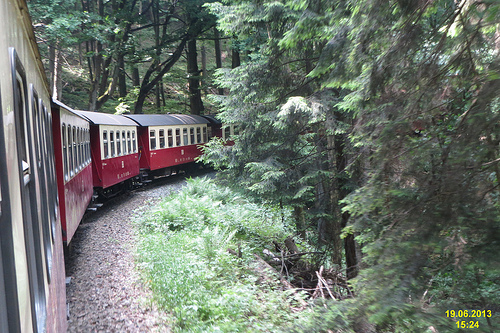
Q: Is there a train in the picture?
A: Yes, there is a train.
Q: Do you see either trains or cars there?
A: Yes, there is a train.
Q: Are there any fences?
A: No, there are no fences.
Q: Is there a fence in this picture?
A: No, there are no fences.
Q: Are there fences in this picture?
A: No, there are no fences.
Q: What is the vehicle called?
A: The vehicle is a train.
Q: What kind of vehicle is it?
A: The vehicle is a train.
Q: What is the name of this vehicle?
A: This is a train.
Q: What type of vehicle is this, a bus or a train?
A: This is a train.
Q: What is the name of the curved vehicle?
A: The vehicle is a train.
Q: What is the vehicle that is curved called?
A: The vehicle is a train.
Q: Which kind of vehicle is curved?
A: The vehicle is a train.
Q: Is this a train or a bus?
A: This is a train.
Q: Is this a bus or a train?
A: This is a train.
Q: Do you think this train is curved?
A: Yes, the train is curved.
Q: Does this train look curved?
A: Yes, the train is curved.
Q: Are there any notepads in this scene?
A: No, there are no notepads.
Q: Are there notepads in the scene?
A: No, there are no notepads.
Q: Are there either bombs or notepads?
A: No, there are no notepads or bombs.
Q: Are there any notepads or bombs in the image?
A: No, there are no notepads or bombs.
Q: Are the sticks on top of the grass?
A: Yes, the sticks are on top of the grass.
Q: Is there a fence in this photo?
A: No, there are no fences.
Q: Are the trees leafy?
A: Yes, the trees are leafy.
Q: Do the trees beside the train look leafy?
A: Yes, the trees are leafy.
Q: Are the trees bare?
A: No, the trees are leafy.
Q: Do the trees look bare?
A: No, the trees are leafy.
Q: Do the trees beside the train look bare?
A: No, the trees are leafy.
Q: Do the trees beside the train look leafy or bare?
A: The trees are leafy.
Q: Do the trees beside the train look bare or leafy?
A: The trees are leafy.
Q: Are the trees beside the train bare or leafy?
A: The trees are leafy.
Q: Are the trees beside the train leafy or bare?
A: The trees are leafy.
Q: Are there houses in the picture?
A: No, there are no houses.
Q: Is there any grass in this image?
A: Yes, there is grass.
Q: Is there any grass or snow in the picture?
A: Yes, there is grass.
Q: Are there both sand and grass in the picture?
A: No, there is grass but no sand.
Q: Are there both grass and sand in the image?
A: No, there is grass but no sand.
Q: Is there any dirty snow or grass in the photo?
A: Yes, there is dirty grass.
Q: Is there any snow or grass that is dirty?
A: Yes, the grass is dirty.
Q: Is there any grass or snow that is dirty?
A: Yes, the grass is dirty.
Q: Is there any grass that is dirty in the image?
A: Yes, there is dirty grass.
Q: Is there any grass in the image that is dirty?
A: Yes, there is grass that is dirty.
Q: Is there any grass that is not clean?
A: Yes, there is dirty grass.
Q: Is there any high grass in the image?
A: Yes, there is high grass.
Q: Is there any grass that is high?
A: Yes, there is grass that is high.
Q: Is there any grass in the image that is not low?
A: Yes, there is high grass.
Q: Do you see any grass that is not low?
A: Yes, there is high grass.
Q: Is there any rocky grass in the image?
A: Yes, there is rocky grass.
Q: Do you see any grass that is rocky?
A: Yes, there is rocky grass.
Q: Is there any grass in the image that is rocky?
A: Yes, there is grass that is rocky.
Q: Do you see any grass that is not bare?
A: Yes, there is rocky grass.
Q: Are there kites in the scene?
A: No, there are no kites.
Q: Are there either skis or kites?
A: No, there are no kites or skis.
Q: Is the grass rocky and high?
A: Yes, the grass is rocky and high.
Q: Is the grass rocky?
A: Yes, the grass is rocky.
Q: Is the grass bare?
A: No, the grass is rocky.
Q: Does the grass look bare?
A: No, the grass is rocky.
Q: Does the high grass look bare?
A: No, the grass is rocky.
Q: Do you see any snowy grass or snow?
A: No, there is grass but it is rocky.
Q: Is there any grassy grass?
A: No, there is grass but it is rocky.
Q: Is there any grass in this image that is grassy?
A: No, there is grass but it is rocky.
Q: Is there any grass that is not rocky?
A: No, there is grass but it is rocky.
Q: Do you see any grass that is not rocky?
A: No, there is grass but it is rocky.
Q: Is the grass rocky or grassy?
A: The grass is rocky.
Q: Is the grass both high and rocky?
A: Yes, the grass is high and rocky.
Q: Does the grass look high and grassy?
A: No, the grass is high but rocky.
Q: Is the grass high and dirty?
A: Yes, the grass is high and dirty.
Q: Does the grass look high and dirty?
A: Yes, the grass is high and dirty.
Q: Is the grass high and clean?
A: No, the grass is high but dirty.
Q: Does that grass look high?
A: Yes, the grass is high.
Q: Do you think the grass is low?
A: No, the grass is high.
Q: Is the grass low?
A: No, the grass is high.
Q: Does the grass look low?
A: No, the grass is high.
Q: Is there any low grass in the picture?
A: No, there is grass but it is high.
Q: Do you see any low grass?
A: No, there is grass but it is high.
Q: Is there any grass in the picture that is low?
A: No, there is grass but it is high.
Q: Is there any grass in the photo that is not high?
A: No, there is grass but it is high.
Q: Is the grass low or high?
A: The grass is high.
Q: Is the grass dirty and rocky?
A: Yes, the grass is dirty and rocky.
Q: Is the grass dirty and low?
A: No, the grass is dirty but high.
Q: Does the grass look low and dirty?
A: No, the grass is dirty but high.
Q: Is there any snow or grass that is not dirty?
A: No, there is grass but it is dirty.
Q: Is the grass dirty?
A: Yes, the grass is dirty.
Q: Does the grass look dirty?
A: Yes, the grass is dirty.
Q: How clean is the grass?
A: The grass is dirty.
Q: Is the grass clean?
A: No, the grass is dirty.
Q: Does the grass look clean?
A: No, the grass is dirty.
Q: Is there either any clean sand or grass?
A: No, there is grass but it is dirty.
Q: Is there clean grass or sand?
A: No, there is grass but it is dirty.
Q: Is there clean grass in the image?
A: No, there is grass but it is dirty.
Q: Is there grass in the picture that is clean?
A: No, there is grass but it is dirty.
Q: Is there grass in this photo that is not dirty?
A: No, there is grass but it is dirty.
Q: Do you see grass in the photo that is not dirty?
A: No, there is grass but it is dirty.